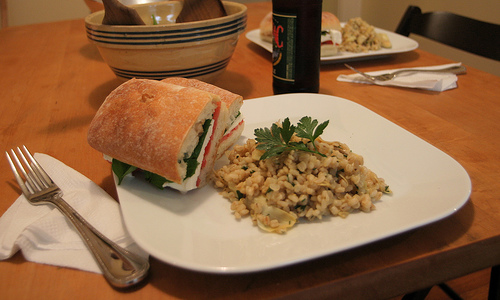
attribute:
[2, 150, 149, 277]
napkin — white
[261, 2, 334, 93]
bottle — Dark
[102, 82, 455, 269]
plate — White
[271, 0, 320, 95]
beer bottle — Dark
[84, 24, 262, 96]
bowl — Ceramic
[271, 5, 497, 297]
chair — brown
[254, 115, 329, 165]
parsley — Green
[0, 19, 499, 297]
table — Brown, wood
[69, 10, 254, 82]
bowl — brown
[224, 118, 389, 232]
rice — Brown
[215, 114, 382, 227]
rice — Brown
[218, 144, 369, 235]
rice — brown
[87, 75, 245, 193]
sandwich — Halved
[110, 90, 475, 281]
plate — White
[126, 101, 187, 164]
bread — Brown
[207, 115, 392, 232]
scrambled eggs — Dry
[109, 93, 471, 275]
dish — White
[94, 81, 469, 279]
plate — White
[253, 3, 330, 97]
bottle — Dark 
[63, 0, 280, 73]
bowl — Ceramic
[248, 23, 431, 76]
plates — White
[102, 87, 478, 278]
plates — White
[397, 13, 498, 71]
chair — Brown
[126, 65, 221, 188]
sandwich — Cut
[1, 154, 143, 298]
fork — Silver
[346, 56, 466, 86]
fork — Silver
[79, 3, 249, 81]
bowl/stripes — Ceramic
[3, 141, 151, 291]
fork — Silver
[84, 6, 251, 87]
bowl — wooden